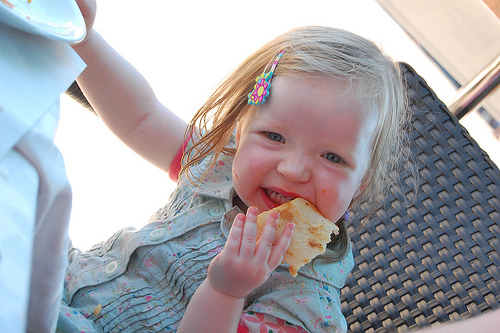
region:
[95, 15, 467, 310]
blond toddler girl eating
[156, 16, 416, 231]
toddler girl with blond hair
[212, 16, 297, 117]
girl with blond hair and one barrette with flowers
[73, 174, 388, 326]
toddler girl holding pizza or bred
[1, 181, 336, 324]
young child with light blue blouse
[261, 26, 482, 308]
toddler eating while relaxing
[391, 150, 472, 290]
green plastic woven outdoor reclining chair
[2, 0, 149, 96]
girl hold light blue plate up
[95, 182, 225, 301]
three buttons on child's shirt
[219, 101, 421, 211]
toddler with eyes squinting into sun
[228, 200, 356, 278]
the baby is eating pizza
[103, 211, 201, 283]
the shirt has white bottons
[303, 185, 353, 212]
there is sauce on the check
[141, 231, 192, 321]
the shirt is decorated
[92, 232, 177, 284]
the shirt is grey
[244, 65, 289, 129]
the hairband is colorful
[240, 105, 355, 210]
the baby is smiling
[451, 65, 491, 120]
the metal is silver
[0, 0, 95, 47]
the plate is empty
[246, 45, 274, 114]
flower barette in girls hair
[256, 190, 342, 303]
girl eating pizza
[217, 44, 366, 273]
little child with pizza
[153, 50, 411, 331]
little girl with hands full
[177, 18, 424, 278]
little girl with string hair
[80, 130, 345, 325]
little girl wearing floral shirt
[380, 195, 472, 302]
black rattan chair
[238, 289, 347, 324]
grey floral shirt dress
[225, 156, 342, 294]
little girl eating food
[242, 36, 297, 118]
brightly colored clip in hair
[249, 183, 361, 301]
A little girl eating pizza.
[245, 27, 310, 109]
A barrette in a little girl hair.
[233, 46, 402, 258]
A little girl smiling.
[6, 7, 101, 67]
A plate on the table.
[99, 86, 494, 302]
A little girl sitting in a chair.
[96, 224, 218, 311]
The shirt has pleads.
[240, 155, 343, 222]
the toddler has food all over her face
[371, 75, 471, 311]
The back of the chair is black.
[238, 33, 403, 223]
The little girl has blonde hair.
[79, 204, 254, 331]
The girl has a blue printed shirt.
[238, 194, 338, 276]
a piece of bread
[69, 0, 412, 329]
a baby eating something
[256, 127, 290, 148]
the eye of a baby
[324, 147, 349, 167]
the eye of a baby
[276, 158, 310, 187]
the nose of a baby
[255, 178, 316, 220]
the mouth of a baby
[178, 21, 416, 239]
the blond hair of a baby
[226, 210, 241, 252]
the finger of a baby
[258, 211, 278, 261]
the finger of a baby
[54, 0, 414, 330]
a smiling baby